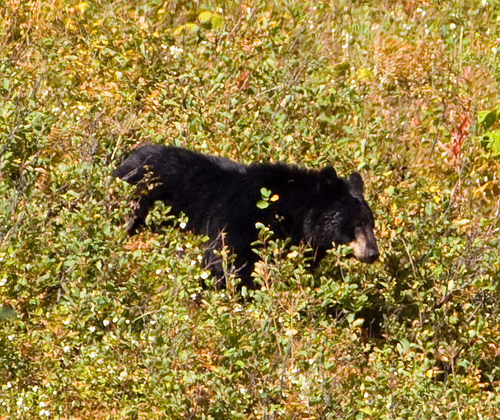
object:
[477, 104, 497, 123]
lea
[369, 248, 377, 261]
nose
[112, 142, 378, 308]
bear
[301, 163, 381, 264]
head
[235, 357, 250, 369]
leaf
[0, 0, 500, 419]
plant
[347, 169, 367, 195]
ear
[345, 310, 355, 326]
leaf